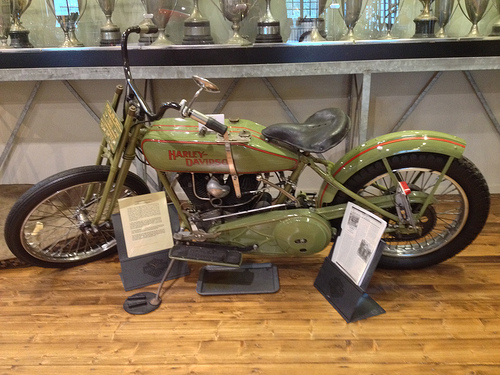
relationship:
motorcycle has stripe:
[5, 25, 490, 305] [142, 125, 299, 175]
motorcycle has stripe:
[5, 25, 490, 305] [319, 137, 463, 202]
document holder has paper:
[112, 204, 191, 292] [118, 191, 175, 257]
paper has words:
[118, 191, 175, 257] [128, 202, 166, 242]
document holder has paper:
[313, 223, 386, 323] [331, 202, 387, 285]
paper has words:
[331, 202, 387, 285] [338, 218, 379, 281]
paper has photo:
[331, 202, 387, 285] [348, 212, 361, 228]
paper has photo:
[331, 202, 387, 285] [357, 240, 372, 262]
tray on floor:
[199, 264, 280, 296] [1, 185, 500, 375]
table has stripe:
[1, 36, 500, 193] [0, 39, 499, 68]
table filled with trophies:
[1, 36, 500, 193] [0, 0, 499, 50]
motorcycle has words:
[5, 25, 490, 305] [169, 149, 229, 166]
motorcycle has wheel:
[5, 25, 490, 305] [4, 165, 150, 267]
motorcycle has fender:
[5, 25, 490, 305] [318, 129, 464, 206]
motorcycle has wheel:
[5, 25, 490, 305] [332, 152, 491, 268]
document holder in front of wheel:
[313, 223, 386, 323] [332, 152, 491, 268]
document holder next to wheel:
[112, 204, 191, 292] [4, 165, 150, 267]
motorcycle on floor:
[5, 25, 490, 305] [1, 185, 500, 375]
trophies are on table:
[0, 0, 499, 50] [1, 36, 500, 193]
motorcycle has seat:
[5, 25, 490, 305] [262, 108, 351, 152]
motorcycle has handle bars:
[5, 25, 490, 305] [122, 26, 227, 135]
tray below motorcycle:
[199, 264, 280, 296] [5, 25, 490, 305]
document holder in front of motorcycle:
[112, 204, 191, 292] [5, 25, 490, 305]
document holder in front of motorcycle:
[313, 223, 386, 323] [5, 25, 490, 305]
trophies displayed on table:
[0, 0, 499, 50] [1, 36, 500, 193]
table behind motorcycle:
[1, 36, 500, 193] [5, 25, 490, 305]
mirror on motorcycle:
[192, 75, 220, 93] [5, 25, 490, 305]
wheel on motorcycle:
[332, 152, 491, 268] [5, 25, 490, 305]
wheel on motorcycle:
[4, 165, 150, 267] [5, 25, 490, 305]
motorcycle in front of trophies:
[5, 25, 490, 305] [0, 0, 499, 50]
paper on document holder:
[331, 202, 387, 285] [313, 223, 386, 323]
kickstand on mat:
[151, 258, 176, 305] [124, 292, 161, 314]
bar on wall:
[0, 56, 499, 81] [1, 69, 500, 194]